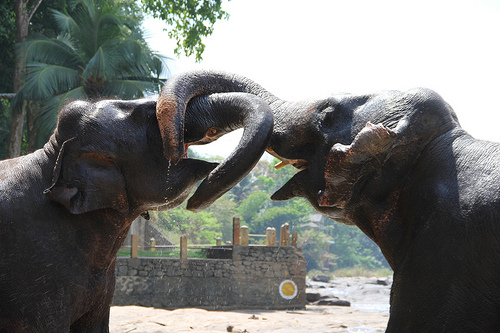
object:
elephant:
[155, 70, 499, 333]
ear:
[317, 121, 400, 211]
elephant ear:
[140, 210, 150, 220]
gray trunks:
[0, 0, 39, 157]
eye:
[317, 105, 339, 125]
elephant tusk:
[180, 93, 274, 214]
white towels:
[157, 59, 292, 226]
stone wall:
[110, 246, 307, 311]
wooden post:
[233, 216, 242, 245]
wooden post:
[283, 222, 290, 247]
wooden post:
[292, 231, 298, 248]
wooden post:
[179, 234, 188, 265]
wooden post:
[131, 234, 139, 258]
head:
[34, 91, 273, 227]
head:
[155, 65, 462, 226]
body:
[0, 153, 119, 330]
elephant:
[0, 90, 273, 333]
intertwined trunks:
[155, 67, 326, 212]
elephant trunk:
[154, 69, 284, 165]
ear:
[41, 135, 129, 218]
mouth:
[259, 144, 311, 201]